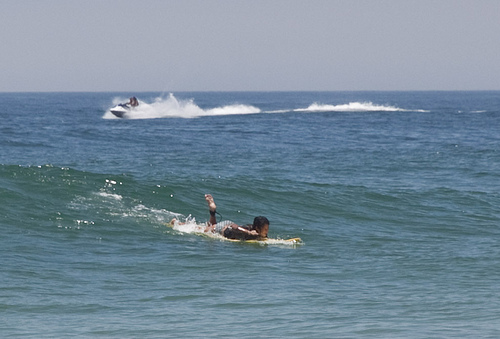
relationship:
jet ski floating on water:
[109, 102, 132, 118] [1, 90, 498, 338]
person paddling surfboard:
[170, 193, 305, 243] [174, 223, 293, 246]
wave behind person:
[1, 163, 207, 216] [170, 193, 305, 243]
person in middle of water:
[170, 193, 305, 243] [1, 90, 498, 338]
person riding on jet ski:
[126, 97, 140, 108] [109, 102, 132, 118]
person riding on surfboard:
[170, 193, 305, 243] [174, 223, 293, 246]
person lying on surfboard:
[170, 193, 305, 243] [174, 223, 293, 246]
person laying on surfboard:
[170, 193, 305, 243] [174, 223, 293, 246]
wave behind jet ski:
[291, 101, 430, 113] [109, 102, 132, 118]